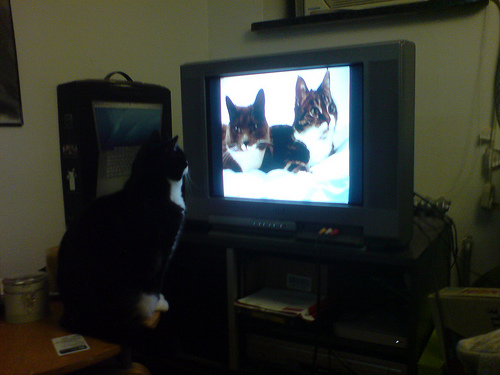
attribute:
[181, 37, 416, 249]
television — large, gray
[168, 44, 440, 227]
tv — old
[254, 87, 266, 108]
ear — brown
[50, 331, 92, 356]
paper — small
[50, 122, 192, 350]
cat — black, white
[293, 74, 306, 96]
ear — brown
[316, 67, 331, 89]
ear — brown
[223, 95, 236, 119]
ear — brown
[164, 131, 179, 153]
ear — brown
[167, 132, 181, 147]
ear — brown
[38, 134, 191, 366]
cat — dark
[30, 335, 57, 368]
table — wooden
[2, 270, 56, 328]
container — small 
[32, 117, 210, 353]
cat — black, white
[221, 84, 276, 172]
cat — brown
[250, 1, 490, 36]
shelf — black